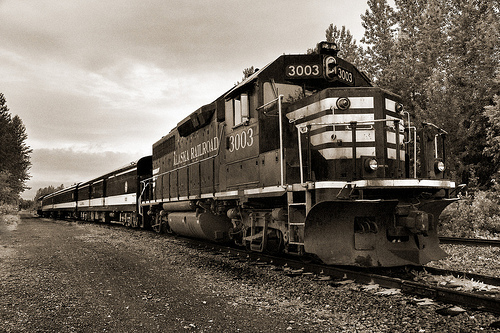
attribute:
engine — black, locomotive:
[145, 38, 470, 270]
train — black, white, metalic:
[32, 39, 457, 276]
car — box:
[75, 146, 147, 230]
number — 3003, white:
[224, 124, 256, 156]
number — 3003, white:
[287, 61, 321, 78]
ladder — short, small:
[281, 183, 320, 252]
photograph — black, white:
[3, 2, 499, 333]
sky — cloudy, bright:
[2, 0, 367, 129]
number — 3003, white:
[336, 67, 356, 85]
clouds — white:
[1, 69, 141, 178]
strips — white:
[281, 92, 376, 162]